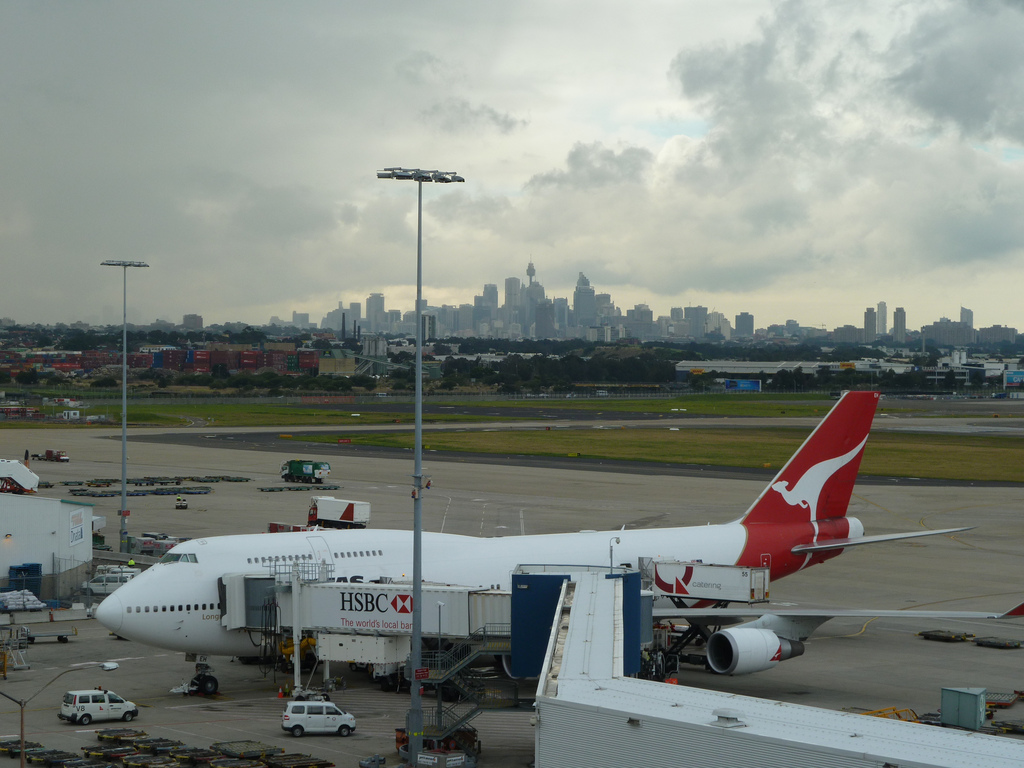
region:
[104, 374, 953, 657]
white and red airplane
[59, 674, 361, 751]
white vans parked near the plane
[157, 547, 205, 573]
cockpit windows on the plane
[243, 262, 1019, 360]
cityscape behind the airport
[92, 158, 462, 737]
tall grey light poles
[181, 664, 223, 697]
front wheels on the plane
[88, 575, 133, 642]
nose of the white airplane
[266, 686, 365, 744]
A vehicle is white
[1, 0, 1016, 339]
The sky is very cloudy and overcast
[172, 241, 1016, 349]
Many buildings in the distance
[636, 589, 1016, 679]
The wing of a plane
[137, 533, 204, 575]
Front windows of a plane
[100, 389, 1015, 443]
A long gray runway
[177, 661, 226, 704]
Black wheels of the plane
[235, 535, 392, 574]
Windows on the side of a plane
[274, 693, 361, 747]
small white mini van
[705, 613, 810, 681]
large jet engine on plane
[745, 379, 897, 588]
tail of large jet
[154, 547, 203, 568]
front window of plane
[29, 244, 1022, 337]
city skyline in the distance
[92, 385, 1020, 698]
large red and white jet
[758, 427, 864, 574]
white kangaroo on tail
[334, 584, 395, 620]
black writing on jetway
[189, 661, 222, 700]
front tire of airplane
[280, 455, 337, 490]
large green truck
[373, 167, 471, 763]
A tall gray light post.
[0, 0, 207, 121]
Part of a thick gray cloud.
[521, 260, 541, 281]
Silhoutte of a tall tower.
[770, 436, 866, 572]
A white kangaroo design.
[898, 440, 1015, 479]
A field of small grass.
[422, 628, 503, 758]
A tall and gray ladder.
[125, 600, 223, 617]
A row of small windows.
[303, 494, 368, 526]
A red head truck with white cargo.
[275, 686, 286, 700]
An orange with gray road cone.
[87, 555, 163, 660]
the nose of a plane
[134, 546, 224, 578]
the front window of a plane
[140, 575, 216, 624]
the windows of a plane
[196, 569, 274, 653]
the entrance of a plane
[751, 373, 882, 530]
the tail fin of a plane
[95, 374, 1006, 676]
the plane is on the tarmac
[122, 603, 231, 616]
a row of windows is on the plane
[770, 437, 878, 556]
a logo is on the tail of the plane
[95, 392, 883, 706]
the plane is painted white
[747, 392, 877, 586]
the tail of the plane is painted red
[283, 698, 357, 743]
the van is painted white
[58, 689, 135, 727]
the van is painted white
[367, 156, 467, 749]
the light pole is made of metal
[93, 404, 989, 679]
the plane is made of metal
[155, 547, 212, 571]
part of an airplane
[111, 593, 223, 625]
part of an airplane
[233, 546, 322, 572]
part of an airplane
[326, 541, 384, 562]
part of an airplane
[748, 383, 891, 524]
part of an airplane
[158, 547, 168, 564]
a window on a plane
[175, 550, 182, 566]
a window on a plane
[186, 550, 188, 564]
a window on a plane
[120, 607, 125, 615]
a window on a plane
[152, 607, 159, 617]
a window on a plane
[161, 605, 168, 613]
a window on a plane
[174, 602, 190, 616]
a window on a plane